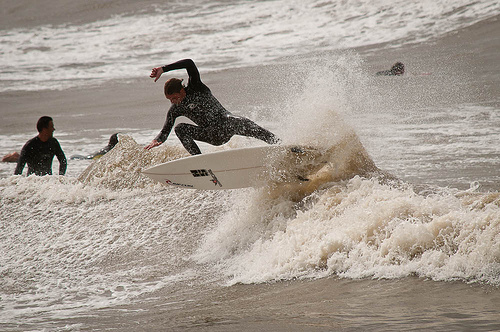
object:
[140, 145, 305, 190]
surfboard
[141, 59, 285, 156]
surfer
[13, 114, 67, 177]
surfer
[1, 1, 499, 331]
water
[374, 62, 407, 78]
swimmer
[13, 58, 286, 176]
group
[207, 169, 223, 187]
writing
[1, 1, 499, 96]
wave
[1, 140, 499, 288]
wave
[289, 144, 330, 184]
tail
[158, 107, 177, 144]
arm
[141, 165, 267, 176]
line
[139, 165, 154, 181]
nose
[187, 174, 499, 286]
foam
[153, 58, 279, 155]
wetsuit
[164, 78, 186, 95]
hair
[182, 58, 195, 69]
elbow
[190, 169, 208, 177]
logo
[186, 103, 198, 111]
decal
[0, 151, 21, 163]
rock